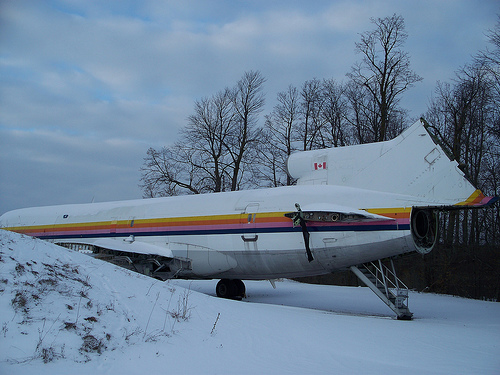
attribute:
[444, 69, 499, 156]
trees — leaveless 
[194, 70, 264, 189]
trees — leaveless 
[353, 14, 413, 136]
trees — leaveless 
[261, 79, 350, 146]
trees — leaveless 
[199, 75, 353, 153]
trees — leaveless 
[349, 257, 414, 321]
ladder — down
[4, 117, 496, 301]
airplane — large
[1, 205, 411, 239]
stripes — colorful, colored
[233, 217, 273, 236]
stripe — pink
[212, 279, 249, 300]
wheel — black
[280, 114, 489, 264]
tail sections — missing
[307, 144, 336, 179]
flag — Canadian 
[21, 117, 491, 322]
plane — white, orange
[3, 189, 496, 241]
stripes — yellow, orange